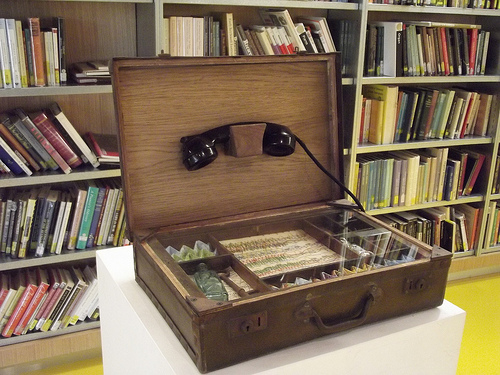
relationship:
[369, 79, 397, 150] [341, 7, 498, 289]
book on shelf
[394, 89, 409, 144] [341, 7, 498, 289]
book on shelf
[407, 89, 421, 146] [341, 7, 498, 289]
book on shelf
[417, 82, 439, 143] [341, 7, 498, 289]
book on shelf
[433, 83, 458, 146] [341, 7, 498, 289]
book on shelf